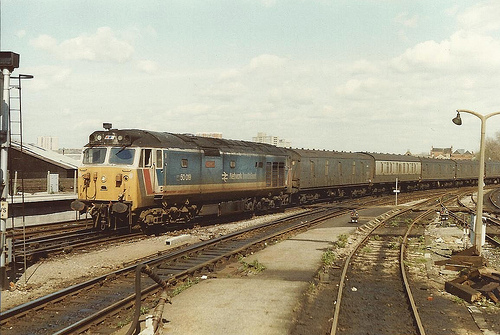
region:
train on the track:
[69, 107, 486, 213]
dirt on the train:
[316, 151, 483, 176]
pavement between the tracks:
[201, 285, 304, 318]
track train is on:
[38, 228, 64, 251]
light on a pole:
[447, 104, 479, 136]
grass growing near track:
[172, 274, 184, 296]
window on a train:
[89, 148, 128, 165]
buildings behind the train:
[205, 126, 290, 150]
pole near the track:
[473, 108, 499, 246]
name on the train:
[205, 166, 259, 188]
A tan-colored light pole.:
[453, 104, 498, 249]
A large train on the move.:
[68, 122, 483, 235]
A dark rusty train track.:
[157, 233, 252, 278]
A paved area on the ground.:
[176, 279, 280, 333]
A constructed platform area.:
[0, 147, 79, 232]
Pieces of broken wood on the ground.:
[441, 262, 483, 301]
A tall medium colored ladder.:
[7, 70, 34, 287]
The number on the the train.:
[177, 171, 195, 183]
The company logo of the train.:
[217, 172, 263, 184]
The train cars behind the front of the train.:
[293, 145, 475, 197]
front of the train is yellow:
[77, 130, 139, 210]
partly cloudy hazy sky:
[0, 1, 499, 155]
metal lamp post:
[452, 108, 499, 261]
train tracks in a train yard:
[5, 188, 498, 333]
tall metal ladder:
[6, 76, 32, 291]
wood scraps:
[434, 253, 499, 311]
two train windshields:
[83, 148, 139, 167]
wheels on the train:
[137, 173, 496, 235]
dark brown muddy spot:
[288, 270, 476, 331]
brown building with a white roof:
[0, 141, 80, 196]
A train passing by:
[71, 132, 485, 203]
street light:
[451, 109, 496, 264]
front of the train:
[75, 127, 157, 214]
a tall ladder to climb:
[8, 70, 24, 305]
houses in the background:
[430, 145, 477, 165]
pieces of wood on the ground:
[433, 247, 494, 308]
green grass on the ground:
[227, 257, 272, 277]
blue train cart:
[160, 150, 290, 191]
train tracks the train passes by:
[105, 247, 226, 282]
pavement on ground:
[146, 283, 301, 333]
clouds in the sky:
[191, 56, 464, 115]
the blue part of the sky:
[166, 6, 348, 47]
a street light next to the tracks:
[449, 110, 493, 259]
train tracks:
[126, 233, 450, 310]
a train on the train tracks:
[67, 122, 494, 239]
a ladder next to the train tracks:
[10, 79, 33, 284]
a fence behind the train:
[10, 178, 72, 197]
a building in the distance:
[33, 134, 59, 148]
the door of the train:
[146, 153, 165, 195]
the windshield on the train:
[106, 146, 132, 162]